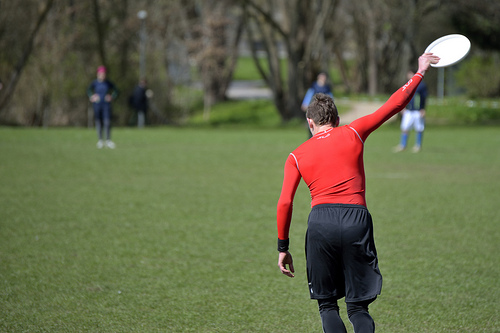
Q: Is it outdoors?
A: Yes, it is outdoors.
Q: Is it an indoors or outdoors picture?
A: It is outdoors.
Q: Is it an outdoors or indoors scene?
A: It is outdoors.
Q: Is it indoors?
A: No, it is outdoors.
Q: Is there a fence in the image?
A: No, there are no fences.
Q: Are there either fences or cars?
A: No, there are no fences or cars.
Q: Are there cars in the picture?
A: No, there are no cars.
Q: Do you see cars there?
A: No, there are no cars.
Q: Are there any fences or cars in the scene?
A: No, there are no cars or fences.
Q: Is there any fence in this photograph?
A: No, there are no fences.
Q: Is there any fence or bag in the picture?
A: No, there are no fences or bags.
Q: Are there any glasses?
A: No, there are no glasses.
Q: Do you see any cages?
A: No, there are no cages.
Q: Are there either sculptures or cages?
A: No, there are no cages or sculptures.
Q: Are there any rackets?
A: No, there are no rackets.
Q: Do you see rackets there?
A: No, there are no rackets.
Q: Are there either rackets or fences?
A: No, there are no rackets or fences.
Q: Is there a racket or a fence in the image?
A: No, there are no rackets or fences.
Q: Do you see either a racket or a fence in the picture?
A: No, there are no rackets or fences.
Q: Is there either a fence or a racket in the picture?
A: No, there are no rackets or fences.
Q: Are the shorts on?
A: Yes, the shorts are on.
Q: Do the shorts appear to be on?
A: Yes, the shorts are on.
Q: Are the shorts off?
A: No, the shorts are on.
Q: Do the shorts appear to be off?
A: No, the shorts are on.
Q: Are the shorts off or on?
A: The shorts are on.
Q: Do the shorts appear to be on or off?
A: The shorts are on.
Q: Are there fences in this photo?
A: No, there are no fences.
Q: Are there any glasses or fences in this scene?
A: No, there are no fences or glasses.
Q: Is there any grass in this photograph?
A: Yes, there is grass.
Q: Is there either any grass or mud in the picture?
A: Yes, there is grass.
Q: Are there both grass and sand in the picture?
A: No, there is grass but no sand.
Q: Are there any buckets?
A: No, there are no buckets.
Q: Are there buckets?
A: No, there are no buckets.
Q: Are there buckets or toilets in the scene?
A: No, there are no buckets or toilets.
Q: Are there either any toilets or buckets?
A: No, there are no buckets or toilets.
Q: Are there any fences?
A: No, there are no fences.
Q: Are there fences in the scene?
A: No, there are no fences.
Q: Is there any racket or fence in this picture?
A: No, there are no fences or rackets.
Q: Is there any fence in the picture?
A: No, there are no fences.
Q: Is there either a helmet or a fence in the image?
A: No, there are no fences or helmets.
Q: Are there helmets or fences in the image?
A: No, there are no fences or helmets.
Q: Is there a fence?
A: No, there are no fences.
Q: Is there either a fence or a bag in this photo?
A: No, there are no fences or bags.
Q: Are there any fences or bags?
A: No, there are no fences or bags.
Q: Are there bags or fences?
A: No, there are no fences or bags.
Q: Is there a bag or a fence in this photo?
A: No, there are no fences or bags.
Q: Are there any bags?
A: No, there are no bags.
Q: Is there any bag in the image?
A: No, there are no bags.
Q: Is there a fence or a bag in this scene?
A: No, there are no bags or fences.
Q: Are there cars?
A: No, there are no cars.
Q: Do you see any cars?
A: No, there are no cars.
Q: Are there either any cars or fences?
A: No, there are no cars or fences.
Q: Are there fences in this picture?
A: No, there are no fences.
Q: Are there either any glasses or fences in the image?
A: No, there are no fences or glasses.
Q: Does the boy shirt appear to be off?
A: No, the shirt is on.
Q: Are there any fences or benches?
A: No, there are no fences or benches.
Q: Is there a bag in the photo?
A: No, there are no bags.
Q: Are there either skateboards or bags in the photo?
A: No, there are no bags or skateboards.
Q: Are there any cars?
A: No, there are no cars.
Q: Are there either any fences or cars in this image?
A: No, there are no cars or fences.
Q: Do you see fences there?
A: No, there are no fences.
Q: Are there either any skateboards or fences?
A: No, there are no fences or skateboards.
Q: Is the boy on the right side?
A: Yes, the boy is on the right of the image.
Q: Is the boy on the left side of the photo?
A: No, the boy is on the right of the image.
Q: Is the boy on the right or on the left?
A: The boy is on the right of the image.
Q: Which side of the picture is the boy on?
A: The boy is on the right of the image.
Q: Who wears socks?
A: The boy wears socks.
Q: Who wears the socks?
A: The boy wears socks.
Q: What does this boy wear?
A: The boy wears socks.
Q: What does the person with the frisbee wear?
A: The boy wears socks.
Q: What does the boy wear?
A: The boy wears socks.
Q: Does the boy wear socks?
A: Yes, the boy wears socks.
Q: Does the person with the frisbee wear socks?
A: Yes, the boy wears socks.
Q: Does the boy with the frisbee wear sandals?
A: No, the boy wears socks.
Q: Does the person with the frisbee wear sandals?
A: No, the boy wears socks.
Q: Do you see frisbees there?
A: Yes, there is a frisbee.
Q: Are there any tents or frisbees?
A: Yes, there is a frisbee.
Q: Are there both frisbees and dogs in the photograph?
A: No, there is a frisbee but no dogs.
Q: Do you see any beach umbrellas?
A: No, there are no beach umbrellas.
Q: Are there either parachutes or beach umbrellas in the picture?
A: No, there are no beach umbrellas or parachutes.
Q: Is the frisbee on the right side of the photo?
A: Yes, the frisbee is on the right of the image.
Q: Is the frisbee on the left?
A: No, the frisbee is on the right of the image.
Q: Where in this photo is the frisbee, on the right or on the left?
A: The frisbee is on the right of the image.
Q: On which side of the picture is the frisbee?
A: The frisbee is on the right of the image.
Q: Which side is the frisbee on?
A: The frisbee is on the right of the image.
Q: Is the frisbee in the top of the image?
A: Yes, the frisbee is in the top of the image.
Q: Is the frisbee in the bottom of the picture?
A: No, the frisbee is in the top of the image.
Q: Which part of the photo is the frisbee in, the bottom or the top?
A: The frisbee is in the top of the image.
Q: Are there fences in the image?
A: No, there are no fences.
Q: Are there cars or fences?
A: No, there are no fences or cars.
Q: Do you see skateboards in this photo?
A: No, there are no skateboards.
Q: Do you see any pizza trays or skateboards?
A: No, there are no skateboards or pizza trays.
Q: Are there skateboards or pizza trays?
A: No, there are no skateboards or pizza trays.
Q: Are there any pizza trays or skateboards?
A: No, there are no skateboards or pizza trays.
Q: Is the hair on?
A: Yes, the hair is on.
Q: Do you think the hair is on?
A: Yes, the hair is on.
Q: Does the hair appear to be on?
A: Yes, the hair is on.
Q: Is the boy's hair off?
A: No, the hair is on.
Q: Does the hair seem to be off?
A: No, the hair is on.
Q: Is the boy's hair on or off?
A: The hair is on.